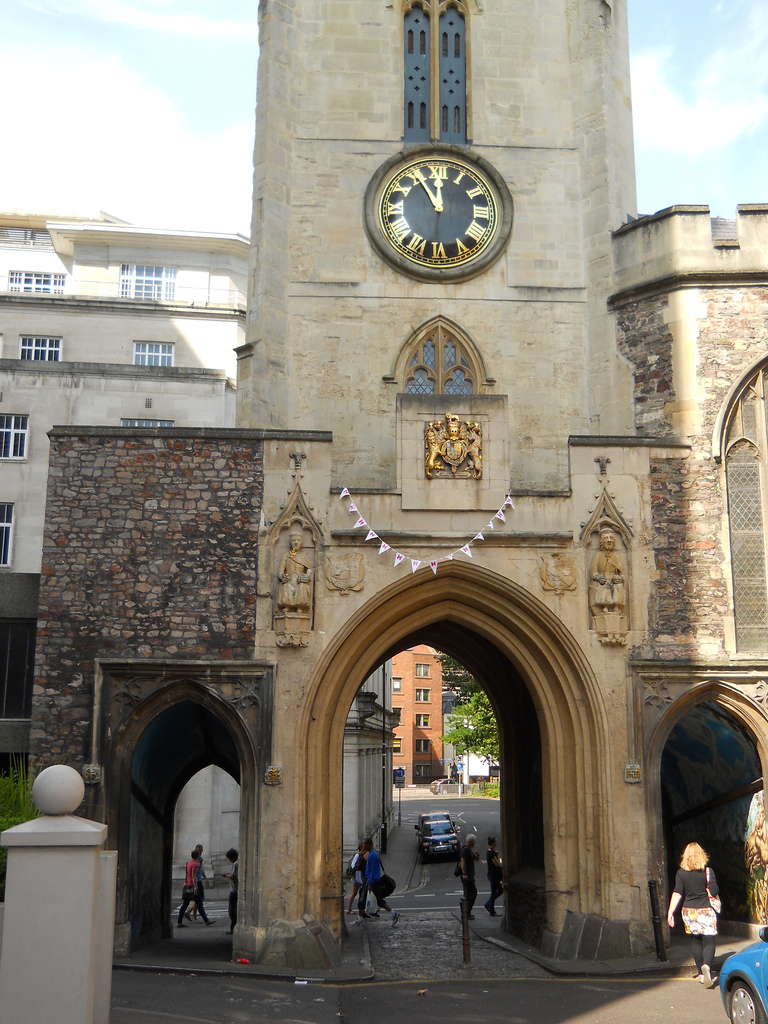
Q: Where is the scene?
A: Near a church.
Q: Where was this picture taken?
A: In a city.